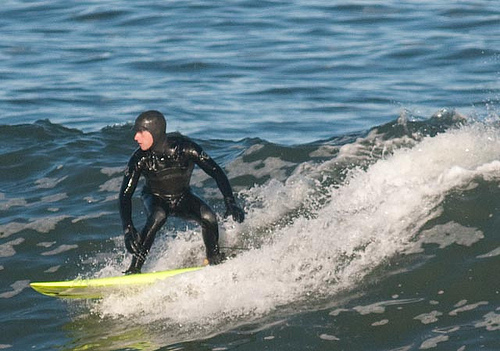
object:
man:
[118, 109, 246, 275]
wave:
[1, 112, 82, 168]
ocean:
[1, 0, 498, 351]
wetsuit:
[118, 109, 246, 277]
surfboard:
[29, 264, 214, 297]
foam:
[312, 140, 341, 160]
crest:
[0, 108, 499, 150]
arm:
[185, 134, 238, 206]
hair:
[130, 124, 146, 132]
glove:
[224, 202, 246, 222]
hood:
[134, 110, 166, 150]